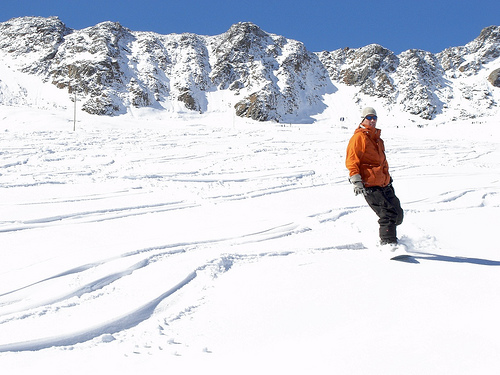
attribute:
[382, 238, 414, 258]
snowboard — white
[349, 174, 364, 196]
glove — grey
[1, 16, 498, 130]
range — snowy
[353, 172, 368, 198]
snow glove — white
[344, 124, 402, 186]
jacket — orange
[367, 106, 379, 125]
beanie — white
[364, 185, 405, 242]
pants — dark colored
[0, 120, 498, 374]
ski slope — snowy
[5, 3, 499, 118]
mountains — covered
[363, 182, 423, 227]
ski pants — black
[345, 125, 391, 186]
jacket — large, orange